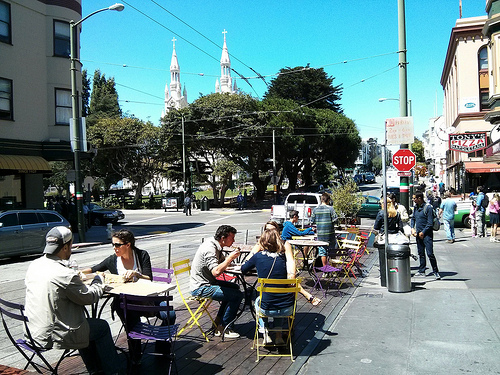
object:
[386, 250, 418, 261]
bag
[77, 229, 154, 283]
woman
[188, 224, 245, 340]
man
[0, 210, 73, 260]
car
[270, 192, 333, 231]
truck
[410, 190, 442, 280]
man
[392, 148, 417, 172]
sign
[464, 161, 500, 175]
awning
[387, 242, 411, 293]
can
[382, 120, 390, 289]
post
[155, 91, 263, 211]
trees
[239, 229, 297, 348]
person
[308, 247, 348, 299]
chair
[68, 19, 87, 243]
pole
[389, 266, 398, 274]
sticker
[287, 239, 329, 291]
table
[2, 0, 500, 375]
city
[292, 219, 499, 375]
street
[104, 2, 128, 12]
light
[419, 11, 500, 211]
building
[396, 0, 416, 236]
pole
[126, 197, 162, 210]
bench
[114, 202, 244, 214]
sidewalk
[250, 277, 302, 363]
chair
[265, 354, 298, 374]
bricks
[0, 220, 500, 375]
sidewalk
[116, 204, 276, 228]
street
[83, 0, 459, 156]
sky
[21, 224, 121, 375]
man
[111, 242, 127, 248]
sunglasses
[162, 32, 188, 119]
spire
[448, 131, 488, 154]
sign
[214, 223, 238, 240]
hair